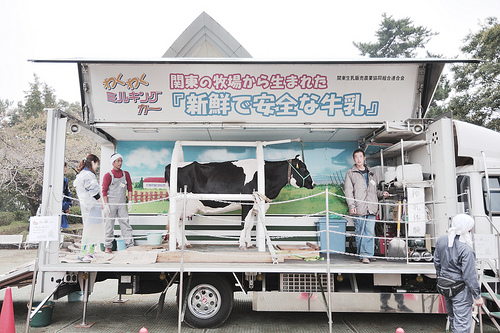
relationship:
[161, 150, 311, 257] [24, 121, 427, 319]
cow on trailer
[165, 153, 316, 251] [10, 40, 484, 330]
cow on truck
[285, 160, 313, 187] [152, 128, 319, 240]
green harness on cow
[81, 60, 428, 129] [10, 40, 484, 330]
sign on truck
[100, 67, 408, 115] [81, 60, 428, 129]
colorful words on sign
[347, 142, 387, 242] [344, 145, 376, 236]
overall on guy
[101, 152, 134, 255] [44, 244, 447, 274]
guy on platform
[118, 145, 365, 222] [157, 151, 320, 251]
scenary behind cow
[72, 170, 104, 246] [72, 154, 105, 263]
jacket on guy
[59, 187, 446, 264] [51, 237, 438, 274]
chain link on platform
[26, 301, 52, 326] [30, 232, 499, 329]
bucket under platform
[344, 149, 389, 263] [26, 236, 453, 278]
guy on platform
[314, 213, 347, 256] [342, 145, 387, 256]
trash can by man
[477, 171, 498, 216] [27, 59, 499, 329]
window on trailer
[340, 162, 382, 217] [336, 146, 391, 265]
coat on man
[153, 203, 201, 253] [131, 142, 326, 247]
legs on cow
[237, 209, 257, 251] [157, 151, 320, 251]
legs on cow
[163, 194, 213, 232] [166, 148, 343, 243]
utters on cow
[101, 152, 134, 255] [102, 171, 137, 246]
guy wearing overalls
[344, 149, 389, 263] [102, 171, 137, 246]
guy wearing overalls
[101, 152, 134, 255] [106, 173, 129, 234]
guy wearing overalls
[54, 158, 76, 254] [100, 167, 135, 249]
person wearing coveralls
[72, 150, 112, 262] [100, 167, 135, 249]
person wearing coveralls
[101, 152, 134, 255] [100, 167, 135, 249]
guy wearing coveralls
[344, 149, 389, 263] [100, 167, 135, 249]
guy wearing coveralls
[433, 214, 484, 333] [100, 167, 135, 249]
guy wearing coveralls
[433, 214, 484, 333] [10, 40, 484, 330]
guy next to truck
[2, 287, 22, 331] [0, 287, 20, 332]
cone in cone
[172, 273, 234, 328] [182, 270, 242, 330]
wheel of truck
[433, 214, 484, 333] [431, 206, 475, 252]
guy wearing t-shirt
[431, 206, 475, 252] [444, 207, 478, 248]
t-shirt on head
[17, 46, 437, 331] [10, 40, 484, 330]
rig of truck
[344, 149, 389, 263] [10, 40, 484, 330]
guy standing in truck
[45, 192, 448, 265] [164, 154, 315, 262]
chain link next cow